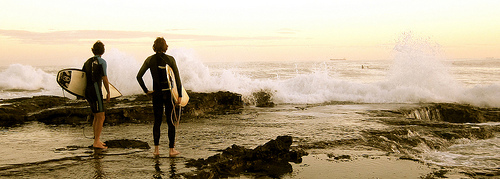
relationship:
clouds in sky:
[1, 29, 301, 47] [4, 2, 496, 67]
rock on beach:
[208, 133, 322, 173] [35, 2, 482, 152]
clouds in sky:
[1, 22, 295, 45] [232, 8, 394, 43]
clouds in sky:
[1, 29, 301, 47] [274, 6, 327, 46]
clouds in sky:
[1, 29, 301, 47] [196, 1, 417, 41]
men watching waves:
[81, 36, 185, 155] [5, 45, 499, 104]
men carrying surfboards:
[33, 25, 206, 157] [50, 67, 125, 99]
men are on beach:
[81, 36, 185, 155] [6, 90, 488, 169]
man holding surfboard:
[86, 42, 109, 64] [51, 67, 89, 89]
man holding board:
[148, 38, 171, 73] [165, 64, 190, 107]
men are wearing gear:
[81, 36, 185, 155] [82, 56, 108, 114]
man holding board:
[83, 40, 112, 148] [55, 67, 122, 100]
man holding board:
[137, 36, 183, 155] [165, 62, 190, 107]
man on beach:
[83, 40, 112, 148] [6, 90, 488, 169]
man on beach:
[137, 36, 183, 155] [6, 90, 488, 169]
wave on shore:
[214, 31, 451, 95] [144, 102, 442, 156]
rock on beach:
[184, 135, 308, 173] [12, 111, 480, 177]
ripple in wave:
[256, 113, 319, 121] [0, 53, 500, 155]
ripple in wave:
[206, 113, 318, 128] [0, 53, 500, 155]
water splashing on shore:
[1, 59, 497, 105] [3, 89, 498, 177]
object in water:
[354, 61, 370, 83] [248, 21, 468, 151]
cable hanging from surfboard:
[168, 100, 182, 134] [169, 82, 189, 109]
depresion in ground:
[420, 99, 499, 130] [370, 97, 497, 175]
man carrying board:
[137, 36, 183, 155] [163, 63, 195, 108]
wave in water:
[0, 30, 500, 106] [1, 48, 498, 175]